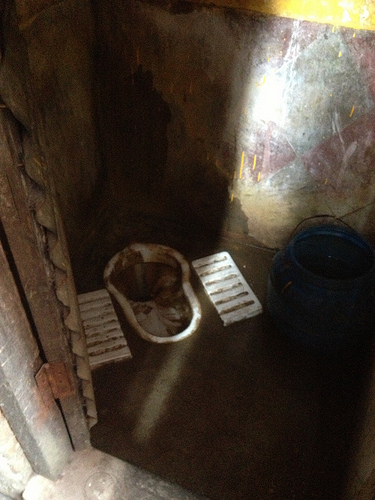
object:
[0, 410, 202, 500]
doorway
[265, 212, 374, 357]
vase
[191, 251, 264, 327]
floor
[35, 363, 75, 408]
hinge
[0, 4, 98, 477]
door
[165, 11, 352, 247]
wall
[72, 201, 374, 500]
floor